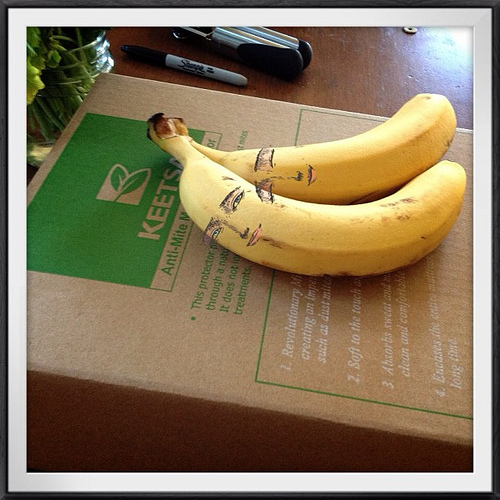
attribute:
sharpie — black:
[169, 40, 209, 87]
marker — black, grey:
[119, 37, 245, 97]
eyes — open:
[200, 180, 251, 248]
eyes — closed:
[235, 134, 293, 202]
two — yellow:
[156, 96, 446, 274]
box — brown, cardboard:
[64, 150, 210, 340]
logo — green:
[50, 100, 182, 303]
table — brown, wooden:
[325, 35, 452, 95]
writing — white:
[292, 285, 450, 380]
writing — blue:
[169, 213, 237, 319]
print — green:
[100, 252, 288, 341]